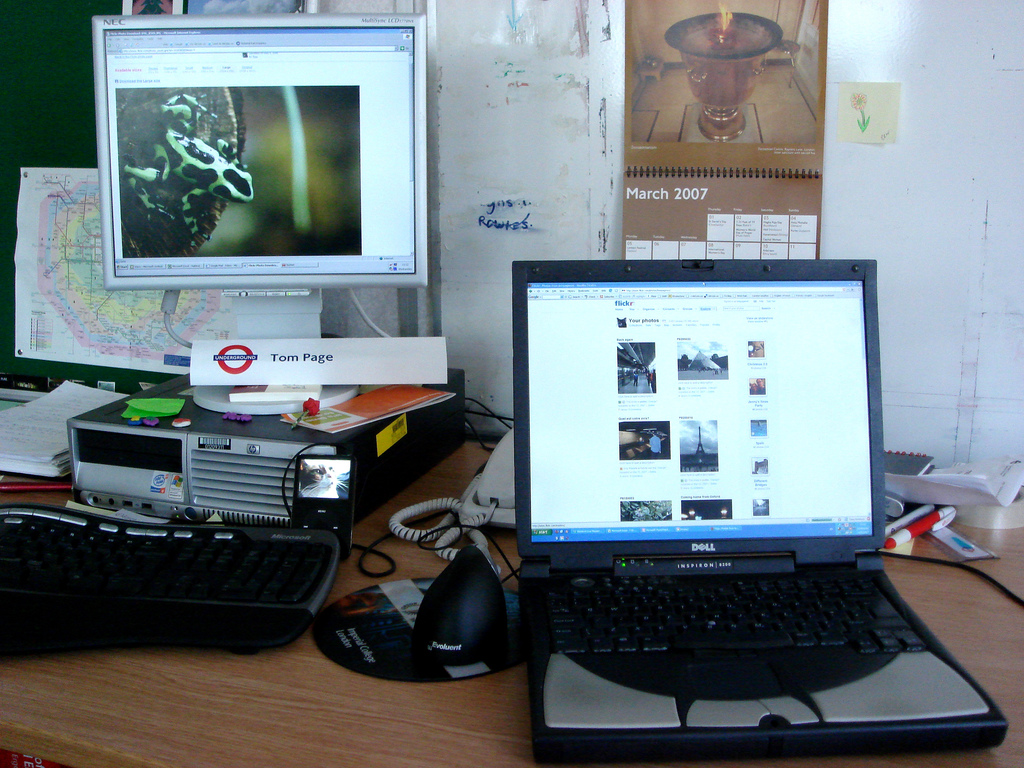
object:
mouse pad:
[312, 577, 529, 685]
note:
[477, 198, 534, 230]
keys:
[65, 544, 150, 592]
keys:
[605, 603, 668, 649]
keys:
[24, 541, 107, 587]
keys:
[792, 600, 850, 644]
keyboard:
[536, 565, 1009, 738]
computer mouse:
[410, 546, 512, 668]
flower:
[290, 397, 322, 431]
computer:
[0, 17, 430, 655]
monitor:
[509, 259, 892, 569]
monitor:
[88, 14, 427, 290]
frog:
[121, 93, 253, 249]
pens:
[882, 505, 959, 552]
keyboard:
[0, 503, 340, 650]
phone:
[388, 424, 516, 572]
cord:
[388, 490, 497, 560]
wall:
[0, 0, 1022, 497]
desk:
[0, 408, 1024, 768]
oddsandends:
[0, 467, 531, 683]